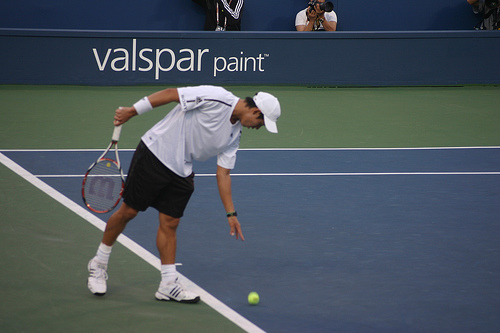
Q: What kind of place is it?
A: It is a pavement.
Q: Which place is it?
A: It is a pavement.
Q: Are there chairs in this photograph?
A: No, there are no chairs.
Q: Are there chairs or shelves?
A: No, there are no chairs or shelves.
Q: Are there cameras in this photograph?
A: Yes, there is a camera.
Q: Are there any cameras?
A: Yes, there is a camera.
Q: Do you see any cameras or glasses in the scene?
A: Yes, there is a camera.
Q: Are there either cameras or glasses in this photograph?
A: Yes, there is a camera.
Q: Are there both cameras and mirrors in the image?
A: No, there is a camera but no mirrors.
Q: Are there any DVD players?
A: No, there are no DVD players.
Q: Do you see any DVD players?
A: No, there are no DVD players.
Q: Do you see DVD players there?
A: No, there are no DVD players.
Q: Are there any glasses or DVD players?
A: No, there are no DVD players or glasses.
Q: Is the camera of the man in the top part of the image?
A: Yes, the camera is in the top of the image.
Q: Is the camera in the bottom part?
A: No, the camera is in the top of the image.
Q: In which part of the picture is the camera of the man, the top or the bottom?
A: The camera is in the top of the image.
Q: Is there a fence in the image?
A: No, there are no fences.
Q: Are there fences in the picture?
A: No, there are no fences.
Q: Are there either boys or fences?
A: No, there are no fences or boys.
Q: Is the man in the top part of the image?
A: Yes, the man is in the top of the image.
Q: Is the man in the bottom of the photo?
A: No, the man is in the top of the image.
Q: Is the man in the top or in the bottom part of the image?
A: The man is in the top of the image.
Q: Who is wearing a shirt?
A: The man is wearing a shirt.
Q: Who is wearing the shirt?
A: The man is wearing a shirt.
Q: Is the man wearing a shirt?
A: Yes, the man is wearing a shirt.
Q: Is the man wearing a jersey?
A: No, the man is wearing a shirt.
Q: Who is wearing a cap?
A: The man is wearing a cap.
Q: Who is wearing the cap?
A: The man is wearing a cap.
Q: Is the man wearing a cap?
A: Yes, the man is wearing a cap.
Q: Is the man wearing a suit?
A: No, the man is wearing a cap.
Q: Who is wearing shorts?
A: The man is wearing shorts.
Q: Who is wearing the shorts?
A: The man is wearing shorts.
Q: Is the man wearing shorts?
A: Yes, the man is wearing shorts.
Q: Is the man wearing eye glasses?
A: No, the man is wearing shorts.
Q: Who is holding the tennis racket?
A: The man is holding the tennis racket.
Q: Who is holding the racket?
A: The man is holding the tennis racket.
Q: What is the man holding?
A: The man is holding the tennis racket.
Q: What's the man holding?
A: The man is holding the tennis racket.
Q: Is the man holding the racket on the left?
A: Yes, the man is holding the tennis racket.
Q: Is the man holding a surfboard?
A: No, the man is holding the tennis racket.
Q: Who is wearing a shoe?
A: The man is wearing a shoe.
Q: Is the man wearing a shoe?
A: Yes, the man is wearing a shoe.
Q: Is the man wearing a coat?
A: No, the man is wearing a shoe.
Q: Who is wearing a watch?
A: The man is wearing a watch.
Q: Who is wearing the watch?
A: The man is wearing a watch.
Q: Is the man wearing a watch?
A: Yes, the man is wearing a watch.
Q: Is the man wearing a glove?
A: No, the man is wearing a watch.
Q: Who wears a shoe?
A: The man wears a shoe.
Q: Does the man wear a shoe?
A: Yes, the man wears a shoe.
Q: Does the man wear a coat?
A: No, the man wears a shoe.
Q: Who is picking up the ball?
A: The man is picking up the ball.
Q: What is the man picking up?
A: The man is picking up the ball.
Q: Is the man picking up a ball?
A: Yes, the man is picking up a ball.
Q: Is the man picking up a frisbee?
A: No, the man is picking up a ball.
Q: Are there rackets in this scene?
A: Yes, there is a racket.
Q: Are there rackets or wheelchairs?
A: Yes, there is a racket.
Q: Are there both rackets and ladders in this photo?
A: No, there is a racket but no ladders.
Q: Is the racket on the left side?
A: Yes, the racket is on the left of the image.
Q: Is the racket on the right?
A: No, the racket is on the left of the image.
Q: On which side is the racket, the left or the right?
A: The racket is on the left of the image.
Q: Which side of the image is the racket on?
A: The racket is on the left of the image.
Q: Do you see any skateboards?
A: No, there are no skateboards.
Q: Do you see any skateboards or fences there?
A: No, there are no skateboards or fences.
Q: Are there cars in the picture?
A: No, there are no cars.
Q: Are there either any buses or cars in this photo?
A: No, there are no cars or buses.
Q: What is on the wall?
A: The sign is on the wall.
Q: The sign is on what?
A: The sign is on the wall.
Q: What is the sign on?
A: The sign is on the wall.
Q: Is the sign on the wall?
A: Yes, the sign is on the wall.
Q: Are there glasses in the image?
A: No, there are no glasses.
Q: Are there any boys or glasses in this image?
A: No, there are no glasses or boys.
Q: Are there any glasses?
A: No, there are no glasses.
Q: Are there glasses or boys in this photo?
A: No, there are no glasses or boys.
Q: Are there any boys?
A: No, there are no boys.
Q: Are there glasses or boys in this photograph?
A: No, there are no boys or glasses.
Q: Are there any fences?
A: No, there are no fences.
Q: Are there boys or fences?
A: No, there are no boys or fences.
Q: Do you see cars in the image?
A: No, there are no cars.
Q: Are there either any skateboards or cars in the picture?
A: No, there are no cars or skateboards.